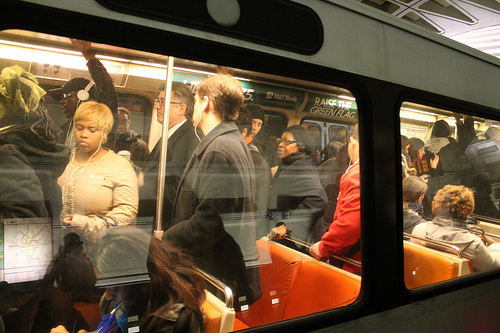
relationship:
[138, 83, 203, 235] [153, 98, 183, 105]
man wearing glasses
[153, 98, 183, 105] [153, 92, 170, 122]
glasses on face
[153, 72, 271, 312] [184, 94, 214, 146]
man wearing headphones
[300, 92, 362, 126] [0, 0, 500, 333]
advertisement inside train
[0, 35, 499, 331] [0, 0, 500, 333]
people inside train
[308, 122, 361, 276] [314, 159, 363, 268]
passenger wears jacket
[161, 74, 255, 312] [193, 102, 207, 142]
man wears headphones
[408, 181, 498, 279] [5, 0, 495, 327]
passenger inside train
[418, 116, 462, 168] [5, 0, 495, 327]
passenger inside train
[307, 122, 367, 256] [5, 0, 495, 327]
passenger inside train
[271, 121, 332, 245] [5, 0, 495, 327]
passenger inside train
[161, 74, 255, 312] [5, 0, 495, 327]
man inside train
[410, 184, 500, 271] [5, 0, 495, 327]
passenger inside train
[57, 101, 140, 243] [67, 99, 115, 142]
people has hair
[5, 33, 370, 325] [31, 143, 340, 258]
window has reflection